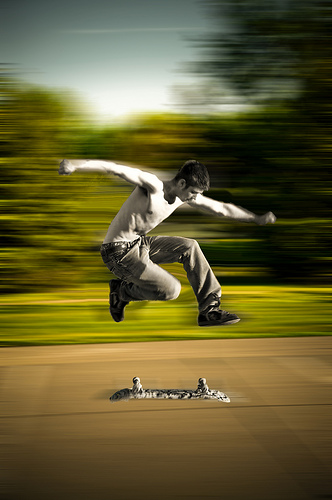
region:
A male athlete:
[53, 134, 283, 336]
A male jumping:
[55, 142, 289, 357]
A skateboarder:
[54, 147, 260, 492]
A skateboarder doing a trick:
[57, 143, 285, 412]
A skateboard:
[105, 371, 235, 409]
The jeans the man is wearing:
[99, 237, 233, 309]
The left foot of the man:
[195, 308, 246, 326]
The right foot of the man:
[103, 275, 136, 327]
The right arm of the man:
[53, 153, 150, 186]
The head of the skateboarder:
[170, 152, 212, 203]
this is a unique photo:
[42, 145, 310, 370]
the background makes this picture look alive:
[20, 157, 299, 351]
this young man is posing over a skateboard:
[48, 148, 279, 326]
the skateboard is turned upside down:
[101, 360, 243, 417]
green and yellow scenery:
[15, 223, 326, 335]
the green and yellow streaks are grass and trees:
[25, 107, 316, 296]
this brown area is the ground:
[14, 351, 305, 476]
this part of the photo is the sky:
[8, 10, 265, 123]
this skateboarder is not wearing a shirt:
[50, 153, 278, 393]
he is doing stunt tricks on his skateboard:
[91, 216, 248, 411]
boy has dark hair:
[173, 149, 204, 189]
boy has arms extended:
[74, 154, 295, 242]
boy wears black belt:
[75, 228, 151, 267]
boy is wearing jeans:
[101, 238, 213, 315]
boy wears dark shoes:
[176, 291, 243, 332]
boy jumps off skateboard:
[118, 374, 276, 424]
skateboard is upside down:
[120, 373, 230, 409]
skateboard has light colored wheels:
[130, 373, 148, 390]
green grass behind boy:
[29, 300, 303, 354]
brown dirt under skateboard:
[19, 412, 277, 486]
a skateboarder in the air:
[49, 134, 311, 441]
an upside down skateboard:
[98, 372, 254, 430]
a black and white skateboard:
[100, 372, 249, 418]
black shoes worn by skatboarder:
[82, 277, 253, 341]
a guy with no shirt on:
[57, 134, 282, 342]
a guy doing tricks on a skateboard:
[35, 141, 299, 341]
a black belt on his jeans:
[87, 240, 145, 264]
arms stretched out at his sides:
[51, 148, 310, 234]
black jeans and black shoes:
[90, 239, 241, 337]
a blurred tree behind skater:
[184, 23, 330, 249]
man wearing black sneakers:
[191, 308, 243, 328]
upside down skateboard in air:
[105, 372, 233, 409]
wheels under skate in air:
[125, 371, 215, 389]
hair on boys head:
[188, 164, 205, 178]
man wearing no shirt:
[126, 208, 143, 226]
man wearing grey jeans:
[140, 273, 163, 282]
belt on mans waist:
[109, 245, 124, 250]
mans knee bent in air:
[85, 270, 183, 323]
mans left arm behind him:
[46, 151, 158, 194]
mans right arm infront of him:
[205, 193, 279, 230]